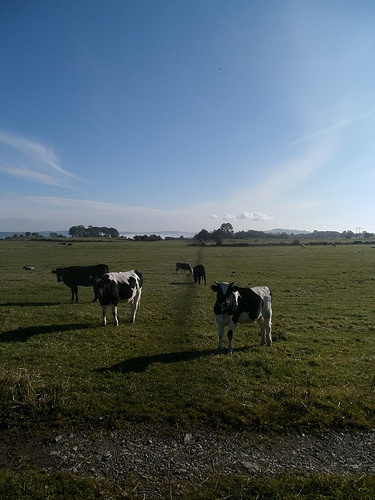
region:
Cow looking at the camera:
[212, 271, 286, 347]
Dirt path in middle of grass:
[46, 416, 361, 481]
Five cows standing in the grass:
[50, 251, 289, 354]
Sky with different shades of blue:
[1, 6, 373, 232]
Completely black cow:
[48, 256, 113, 305]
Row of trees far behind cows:
[6, 227, 372, 243]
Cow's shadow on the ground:
[94, 337, 236, 367]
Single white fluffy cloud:
[207, 203, 271, 227]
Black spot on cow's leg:
[223, 329, 231, 340]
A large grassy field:
[1, 236, 371, 498]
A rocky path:
[0, 419, 370, 479]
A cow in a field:
[207, 278, 281, 355]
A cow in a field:
[191, 265, 209, 284]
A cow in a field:
[171, 260, 194, 277]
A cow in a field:
[91, 266, 147, 328]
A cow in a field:
[49, 260, 111, 304]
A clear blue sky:
[0, 0, 374, 236]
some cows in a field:
[49, 260, 278, 351]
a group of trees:
[68, 221, 120, 238]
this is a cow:
[211, 272, 279, 345]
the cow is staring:
[208, 275, 278, 349]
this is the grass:
[159, 342, 281, 416]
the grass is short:
[305, 242, 367, 356]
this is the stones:
[163, 426, 262, 475]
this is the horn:
[229, 278, 236, 283]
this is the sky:
[84, 5, 295, 141]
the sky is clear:
[95, 12, 250, 132]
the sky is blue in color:
[85, 10, 256, 116]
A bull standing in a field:
[208, 278, 271, 350]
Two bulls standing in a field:
[50, 260, 140, 324]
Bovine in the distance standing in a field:
[52, 240, 69, 243]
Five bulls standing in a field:
[49, 260, 269, 351]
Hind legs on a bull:
[255, 281, 272, 343]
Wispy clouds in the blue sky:
[1, 129, 92, 195]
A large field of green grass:
[4, 244, 374, 430]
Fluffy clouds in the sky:
[208, 211, 271, 220]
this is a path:
[88, 429, 362, 486]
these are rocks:
[42, 436, 100, 481]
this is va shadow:
[115, 354, 187, 371]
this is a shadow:
[16, 313, 75, 341]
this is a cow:
[49, 263, 87, 294]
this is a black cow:
[52, 267, 88, 294]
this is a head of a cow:
[206, 273, 238, 316]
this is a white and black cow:
[212, 276, 292, 348]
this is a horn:
[226, 280, 233, 288]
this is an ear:
[233, 285, 240, 297]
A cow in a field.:
[211, 275, 282, 350]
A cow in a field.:
[94, 268, 146, 318]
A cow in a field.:
[42, 254, 117, 301]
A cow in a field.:
[173, 261, 194, 273]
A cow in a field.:
[22, 263, 37, 270]